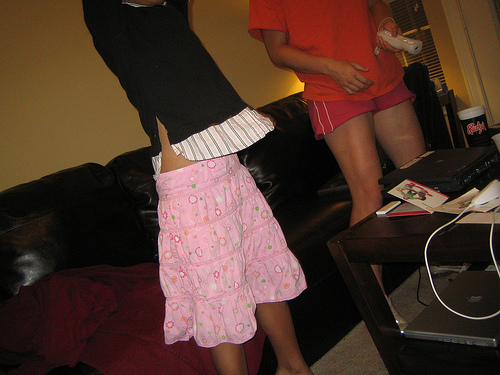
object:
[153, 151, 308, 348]
skirt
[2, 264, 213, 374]
fabric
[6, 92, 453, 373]
couch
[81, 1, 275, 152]
top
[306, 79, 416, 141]
shorts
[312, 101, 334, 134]
stripes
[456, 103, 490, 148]
cup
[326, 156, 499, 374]
table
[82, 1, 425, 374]
people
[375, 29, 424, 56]
controller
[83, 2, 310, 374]
girl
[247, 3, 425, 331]
girl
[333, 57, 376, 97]
right hand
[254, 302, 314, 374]
left leg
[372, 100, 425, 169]
left leg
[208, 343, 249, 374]
right leg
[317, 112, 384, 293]
right leg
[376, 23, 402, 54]
left hand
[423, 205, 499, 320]
cord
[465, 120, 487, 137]
writing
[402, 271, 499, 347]
laptop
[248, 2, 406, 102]
shirt